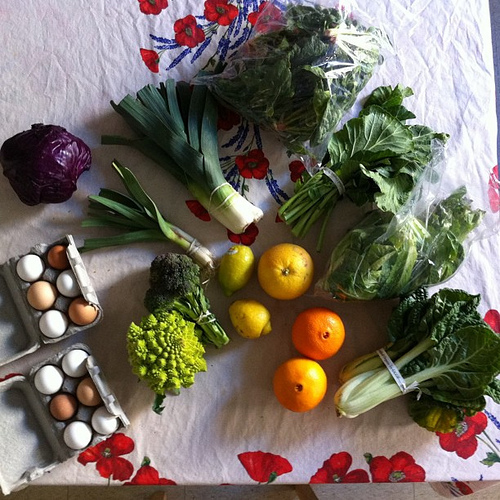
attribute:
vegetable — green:
[341, 310, 491, 425]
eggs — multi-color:
[29, 247, 88, 335]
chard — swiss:
[207, 3, 390, 153]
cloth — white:
[22, 41, 69, 95]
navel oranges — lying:
[265, 302, 350, 419]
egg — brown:
[0, 221, 162, 492]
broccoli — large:
[131, 240, 287, 360]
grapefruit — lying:
[256, 239, 316, 302]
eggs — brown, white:
[34, 349, 120, 454]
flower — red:
[235, 446, 296, 484]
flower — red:
[75, 427, 139, 477]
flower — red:
[307, 443, 368, 484]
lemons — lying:
[199, 226, 275, 346]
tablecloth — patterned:
[16, 12, 151, 96]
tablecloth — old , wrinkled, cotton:
[3, 1, 498, 498]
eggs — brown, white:
[14, 253, 96, 328]